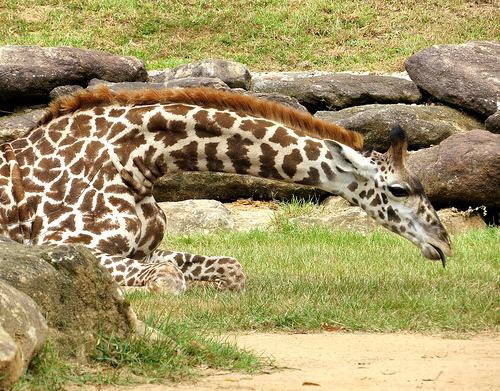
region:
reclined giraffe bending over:
[48, 78, 451, 273]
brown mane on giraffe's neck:
[166, 93, 309, 121]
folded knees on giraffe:
[148, 251, 251, 303]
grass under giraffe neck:
[273, 248, 359, 300]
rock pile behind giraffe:
[337, 84, 469, 126]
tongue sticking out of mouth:
[431, 241, 456, 272]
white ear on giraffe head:
[314, 135, 369, 177]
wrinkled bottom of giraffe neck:
[121, 159, 168, 199]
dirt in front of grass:
[293, 331, 415, 377]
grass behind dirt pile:
[265, 9, 407, 56]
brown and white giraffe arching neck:
[0, 67, 460, 308]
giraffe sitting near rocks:
[4, 68, 455, 314]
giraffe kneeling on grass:
[0, 74, 460, 306]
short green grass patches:
[0, 0, 499, 387]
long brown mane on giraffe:
[36, 85, 376, 152]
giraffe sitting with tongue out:
[2, 70, 467, 286]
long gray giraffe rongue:
[430, 244, 452, 271]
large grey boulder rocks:
[6, 37, 499, 372]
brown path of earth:
[123, 310, 498, 390]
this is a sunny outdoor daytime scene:
[6, 4, 498, 384]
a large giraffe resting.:
[36, 16, 475, 322]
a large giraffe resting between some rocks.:
[12, 47, 479, 317]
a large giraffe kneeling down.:
[8, 16, 477, 327]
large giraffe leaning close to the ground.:
[63, 34, 476, 320]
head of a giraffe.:
[356, 122, 461, 298]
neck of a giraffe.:
[149, 70, 334, 221]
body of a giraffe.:
[12, 103, 151, 249]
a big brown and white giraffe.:
[14, 78, 462, 265]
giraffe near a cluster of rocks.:
[22, 22, 474, 264]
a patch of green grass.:
[260, 251, 419, 323]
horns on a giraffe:
[376, 118, 418, 173]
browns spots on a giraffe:
[38, 122, 94, 189]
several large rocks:
[0, 59, 472, 106]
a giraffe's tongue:
[413, 221, 455, 276]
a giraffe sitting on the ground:
[0, 122, 435, 303]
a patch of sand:
[339, 320, 490, 389]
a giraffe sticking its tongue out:
[322, 142, 476, 292]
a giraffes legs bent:
[107, 228, 242, 313]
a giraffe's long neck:
[102, 71, 382, 238]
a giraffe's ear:
[315, 133, 359, 193]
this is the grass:
[6, 0, 498, 34]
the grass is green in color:
[187, 10, 319, 34]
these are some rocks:
[434, 46, 478, 173]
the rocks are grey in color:
[423, 56, 469, 81]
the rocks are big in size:
[426, 42, 492, 180]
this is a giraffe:
[5, 96, 451, 256]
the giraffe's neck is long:
[128, 100, 324, 182]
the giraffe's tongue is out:
[435, 245, 451, 270]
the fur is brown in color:
[55, 147, 116, 227]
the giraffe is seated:
[19, 102, 446, 294]